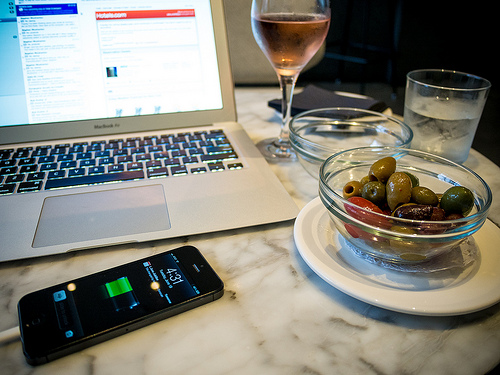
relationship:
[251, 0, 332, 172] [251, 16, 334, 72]
glass with wine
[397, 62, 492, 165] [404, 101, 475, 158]
glass with ice water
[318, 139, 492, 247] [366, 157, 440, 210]
bowl of olives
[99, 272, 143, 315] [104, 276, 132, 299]
battery with green bar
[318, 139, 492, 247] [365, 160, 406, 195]
bowl of fruit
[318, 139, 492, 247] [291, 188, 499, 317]
bowl on a dish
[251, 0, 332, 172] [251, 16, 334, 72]
glass of wine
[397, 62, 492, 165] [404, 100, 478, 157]
glass of ice water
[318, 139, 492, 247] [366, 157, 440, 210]
bowl full of olives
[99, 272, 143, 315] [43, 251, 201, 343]
battery on screen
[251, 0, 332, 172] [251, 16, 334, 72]
glass full of wine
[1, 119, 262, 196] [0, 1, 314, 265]
keyboard of a laptop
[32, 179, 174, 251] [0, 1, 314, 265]
touchpad of a laptop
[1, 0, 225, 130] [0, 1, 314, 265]
screen of a laptop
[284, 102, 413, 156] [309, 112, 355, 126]
bowl made of glass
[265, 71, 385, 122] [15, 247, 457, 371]
napkins on a table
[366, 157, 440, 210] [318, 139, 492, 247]
olives in a glass bowl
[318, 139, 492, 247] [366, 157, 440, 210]
bowl of green olives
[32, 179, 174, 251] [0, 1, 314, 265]
mouse pad for a laptop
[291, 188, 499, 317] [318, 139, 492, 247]
dish holding bowl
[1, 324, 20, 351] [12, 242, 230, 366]
battery cable for phone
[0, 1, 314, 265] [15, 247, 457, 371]
laptop on table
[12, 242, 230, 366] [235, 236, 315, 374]
phone on counter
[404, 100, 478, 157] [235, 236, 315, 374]
ice water on counter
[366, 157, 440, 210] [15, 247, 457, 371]
olives on table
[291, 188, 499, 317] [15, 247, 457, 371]
dish on table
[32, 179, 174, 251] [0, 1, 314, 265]
scroll pad on laptop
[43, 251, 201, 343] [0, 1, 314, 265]
screen on laptop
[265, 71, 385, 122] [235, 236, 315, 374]
napkins on counter